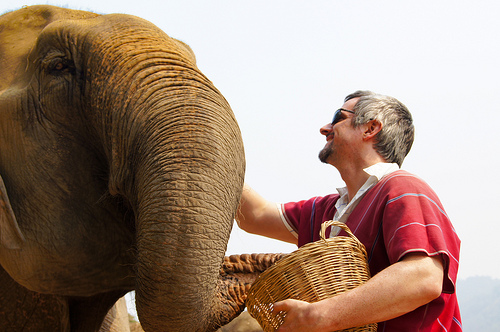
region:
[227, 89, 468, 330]
a man holding a brown basket.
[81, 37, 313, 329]
an elephant's trunk.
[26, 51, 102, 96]
an elephant's right eye.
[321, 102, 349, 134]
a pair of dark sunglasses.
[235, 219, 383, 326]
a brown basket.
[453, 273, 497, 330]
a tree covered hillside.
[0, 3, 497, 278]
a hazy gray sky.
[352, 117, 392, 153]
the left ear of a man.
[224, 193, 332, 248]
a human right arm.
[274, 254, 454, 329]
a left human arm.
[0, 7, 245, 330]
a brown elephant eating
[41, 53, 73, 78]
the elephants eye is brown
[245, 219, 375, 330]
a brown wicker basket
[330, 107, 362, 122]
the man is wearing black framed sunglasses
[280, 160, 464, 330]
the man is wearing a red and white polo shirt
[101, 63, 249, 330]
the elephants trunk is brown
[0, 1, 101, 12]
small hairs on the elephants head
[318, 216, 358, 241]
the baskets wicker handle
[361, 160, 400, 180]
the mans shirt has a white collar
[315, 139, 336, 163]
the man has a goatee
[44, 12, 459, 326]
Man with an elephant.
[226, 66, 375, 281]
Man holding a basket.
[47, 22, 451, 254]
Elephant by the man.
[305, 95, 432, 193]
Man with sunglasses.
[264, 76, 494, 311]
Man in a red shirt.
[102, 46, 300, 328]
Trunk on the elephant.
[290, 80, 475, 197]
Man with gray hair.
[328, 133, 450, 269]
Red shirt with white stripes.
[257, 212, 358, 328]
Wooden basket with the man.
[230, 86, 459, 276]
Man touching an elephant.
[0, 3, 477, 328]
person pats pachyderm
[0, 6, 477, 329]
a large elephant & a regular size middle aged man share a basketful of something+a basketful of dreams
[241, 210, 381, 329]
the tangible basket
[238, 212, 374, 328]
the tangible basket is wicker; a hand holds it, & it has a trunk in it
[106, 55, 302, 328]
not the whole trunk, the rest of the trunk is here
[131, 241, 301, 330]
the bottom of the trunk, before reaching & reaching into the basket, is twisty. & bendy. & lightly meandering.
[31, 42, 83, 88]
a clever eye, brown+long lashed, takes in a photographing newcomer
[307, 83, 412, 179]
grey hair, greyish beard, black sunglasses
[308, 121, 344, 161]
a happy man, whose smile shows it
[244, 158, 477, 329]
baggy red shirt atop white collared shirt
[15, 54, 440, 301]
man touching elephant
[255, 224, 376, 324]
light brown wicker basket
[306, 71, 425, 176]
man wearing black sunglasses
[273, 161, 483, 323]
man wearing red shirt with stripes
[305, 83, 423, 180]
man with graying hair and a goatee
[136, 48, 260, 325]
large tusk of elephant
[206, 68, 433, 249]
man smiling while touching elephant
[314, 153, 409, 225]
white collar of man's shirt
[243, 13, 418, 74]
clear white sky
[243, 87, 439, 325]
man holding wicker basket